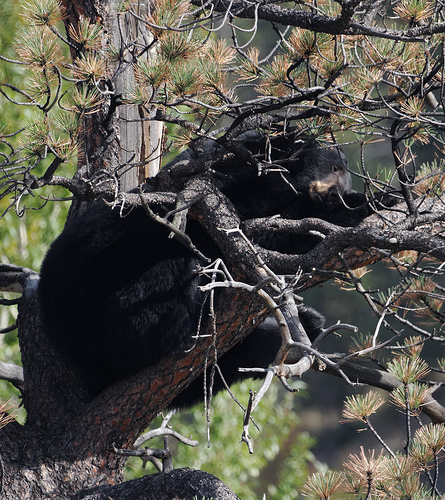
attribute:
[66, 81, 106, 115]
pine — brown, green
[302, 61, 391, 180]
branches — curvy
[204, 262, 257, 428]
branch — broken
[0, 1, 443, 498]
tree — pine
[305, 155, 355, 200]
muzzle — brown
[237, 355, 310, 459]
branch — dead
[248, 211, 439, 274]
branch — crooked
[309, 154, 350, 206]
face — tan, black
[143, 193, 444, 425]
branch — empty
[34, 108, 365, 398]
bear — black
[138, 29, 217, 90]
pine — green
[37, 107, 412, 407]
bear — black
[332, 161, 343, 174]
eye — black